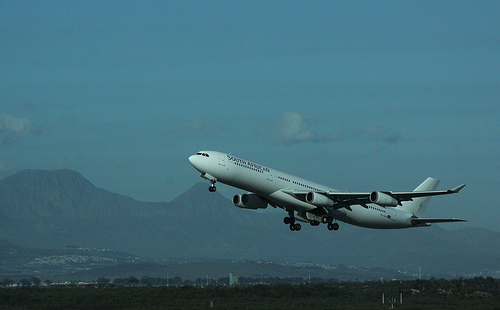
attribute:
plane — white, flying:
[160, 132, 473, 242]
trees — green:
[0, 280, 379, 295]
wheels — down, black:
[267, 215, 350, 235]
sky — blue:
[17, 1, 487, 113]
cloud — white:
[274, 108, 330, 157]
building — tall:
[221, 267, 236, 290]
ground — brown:
[1, 294, 485, 308]